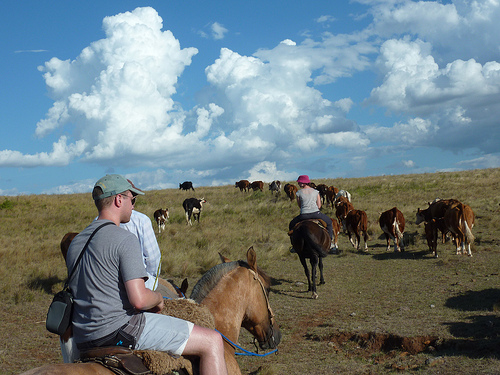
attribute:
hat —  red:
[296, 174, 311, 184]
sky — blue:
[7, 0, 499, 167]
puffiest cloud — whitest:
[33, 5, 223, 167]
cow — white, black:
[183, 197, 202, 226]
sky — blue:
[1, 0, 499, 197]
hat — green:
[86, 162, 144, 197]